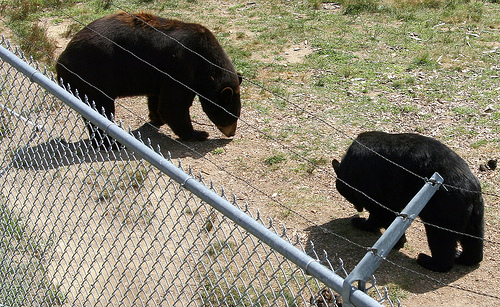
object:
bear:
[54, 14, 244, 150]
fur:
[56, 13, 243, 148]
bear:
[330, 130, 485, 272]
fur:
[331, 131, 485, 274]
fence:
[0, 35, 402, 306]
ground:
[4, 1, 499, 306]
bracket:
[341, 171, 445, 303]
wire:
[106, 2, 499, 200]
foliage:
[463, 34, 474, 47]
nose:
[228, 131, 236, 137]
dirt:
[1, 0, 498, 304]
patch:
[103, 12, 176, 28]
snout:
[213, 122, 238, 137]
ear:
[221, 86, 234, 100]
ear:
[237, 72, 243, 85]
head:
[200, 71, 244, 137]